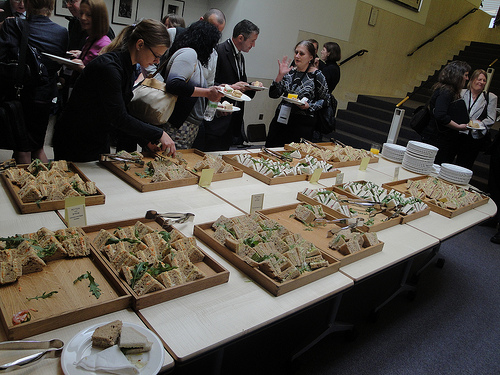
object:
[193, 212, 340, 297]
box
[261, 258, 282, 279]
sandwich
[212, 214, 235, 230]
sandwich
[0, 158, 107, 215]
box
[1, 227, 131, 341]
box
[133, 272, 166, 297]
sandwiches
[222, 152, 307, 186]
box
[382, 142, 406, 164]
stack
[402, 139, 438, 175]
stack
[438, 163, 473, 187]
stack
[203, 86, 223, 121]
bottle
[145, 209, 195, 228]
prongs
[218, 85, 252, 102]
plate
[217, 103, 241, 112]
plate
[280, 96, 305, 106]
plate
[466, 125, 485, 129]
plate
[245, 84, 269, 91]
plate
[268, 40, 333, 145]
woman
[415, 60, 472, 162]
woman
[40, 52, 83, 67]
plate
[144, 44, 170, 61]
pair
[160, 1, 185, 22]
picture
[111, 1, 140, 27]
picture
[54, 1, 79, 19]
picture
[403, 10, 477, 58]
black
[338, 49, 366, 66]
rail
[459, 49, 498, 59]
stair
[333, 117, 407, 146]
stair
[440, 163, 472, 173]
plates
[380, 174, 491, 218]
boxes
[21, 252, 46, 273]
shape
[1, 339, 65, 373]
tong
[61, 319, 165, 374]
plate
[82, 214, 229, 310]
tray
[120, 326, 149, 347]
sandwich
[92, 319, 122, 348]
sandwich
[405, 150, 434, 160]
plates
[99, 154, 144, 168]
tong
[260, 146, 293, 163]
tong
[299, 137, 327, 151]
tong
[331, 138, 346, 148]
tong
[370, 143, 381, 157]
glass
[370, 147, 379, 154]
juice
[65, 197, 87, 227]
card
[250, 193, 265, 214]
card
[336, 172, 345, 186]
card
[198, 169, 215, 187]
card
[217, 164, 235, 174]
sandwiches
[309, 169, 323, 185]
card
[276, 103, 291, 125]
badge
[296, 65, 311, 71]
neck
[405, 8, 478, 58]
railing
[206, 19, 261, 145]
man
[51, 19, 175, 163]
woman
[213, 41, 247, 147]
suit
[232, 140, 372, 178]
eat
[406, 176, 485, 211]
food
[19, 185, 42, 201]
triangle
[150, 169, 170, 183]
sandwich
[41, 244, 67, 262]
triangle